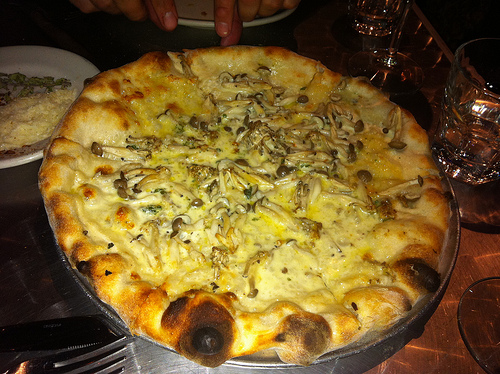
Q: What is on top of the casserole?
A: Mushrooms.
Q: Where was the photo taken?
A: At a table.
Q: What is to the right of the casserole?
A: Glasses.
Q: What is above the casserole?
A: Fingers.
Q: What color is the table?
A: Brown.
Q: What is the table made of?
A: Wood.